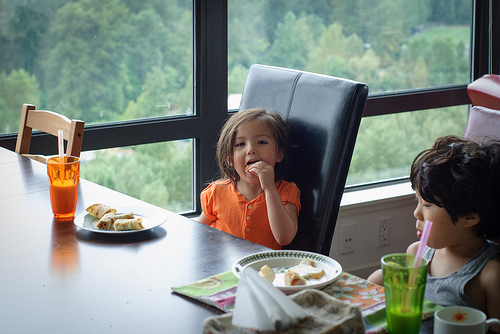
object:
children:
[463, 73, 500, 304]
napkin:
[229, 265, 310, 333]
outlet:
[339, 222, 358, 255]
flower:
[357, 288, 387, 303]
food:
[84, 201, 144, 231]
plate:
[72, 202, 169, 234]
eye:
[234, 141, 246, 148]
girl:
[196, 106, 302, 251]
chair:
[223, 62, 371, 257]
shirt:
[198, 177, 303, 250]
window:
[0, 0, 204, 132]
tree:
[38, 3, 138, 121]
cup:
[378, 253, 429, 334]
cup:
[44, 154, 80, 222]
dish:
[71, 204, 169, 235]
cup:
[429, 304, 499, 334]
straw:
[57, 129, 64, 183]